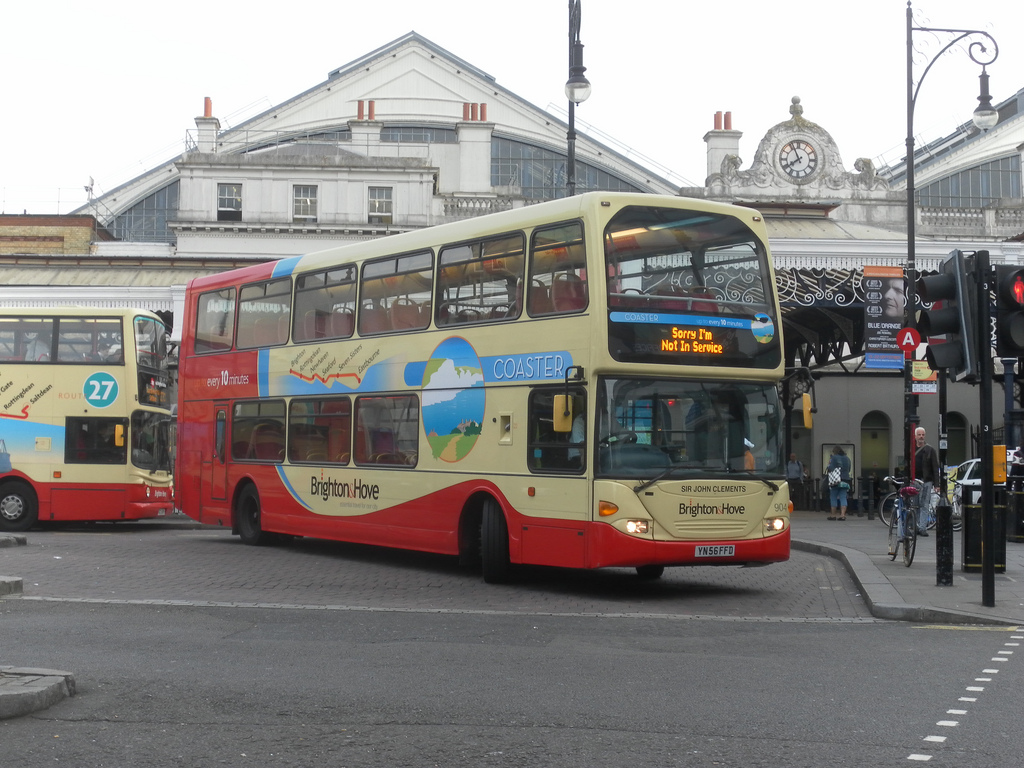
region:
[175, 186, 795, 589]
A red and beige double deck bus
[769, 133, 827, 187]
roman numeral clock on top of a building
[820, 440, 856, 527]
a woman wearing blue and carrying a white hand bag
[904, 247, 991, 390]
a three color traffic light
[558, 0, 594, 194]
street light with a hanging glass globe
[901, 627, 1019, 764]
white crosswalk lines painted on the street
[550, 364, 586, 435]
side view mirror of a double deck bus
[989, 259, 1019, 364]
a two color traffic light with the red light on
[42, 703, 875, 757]
long crack in the middle of the street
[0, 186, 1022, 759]
Two double decker buses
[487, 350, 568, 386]
Word coaster on the side of the bus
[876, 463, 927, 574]
bicycle on the sidewalk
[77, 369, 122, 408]
Number 27 on the bus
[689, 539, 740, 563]
White and black rectangular licence plate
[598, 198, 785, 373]
Windshield on the upper deck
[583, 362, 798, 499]
Windshield has two wipers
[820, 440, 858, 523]
Woman is standing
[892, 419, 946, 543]
Guy wearing jeans standing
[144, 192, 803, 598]
double deck bus on road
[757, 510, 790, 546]
left headlight on bus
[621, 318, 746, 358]
display module on bus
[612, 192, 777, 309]
top deck windshield on bus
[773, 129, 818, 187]
clock on building behind bus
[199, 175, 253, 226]
window on the building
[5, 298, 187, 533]
Yellow and red bus is double decker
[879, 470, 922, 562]
Bike chained to a pole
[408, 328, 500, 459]
advertisement on the bus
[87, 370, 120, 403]
number 27 on the bus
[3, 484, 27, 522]
silver rim on the bus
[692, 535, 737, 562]
license plate on the bus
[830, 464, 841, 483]
woman holding a black and white purse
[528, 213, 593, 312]
glass window on the yellow bus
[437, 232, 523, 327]
glass window on the yellow bus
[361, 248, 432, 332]
glass window on the yellow bus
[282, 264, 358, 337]
glass window on the yellow bus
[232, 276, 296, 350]
glass window on the yellow bus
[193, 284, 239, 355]
glass window on the yellow bus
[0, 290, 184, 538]
a bus with the number 27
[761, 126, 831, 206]
a clock on the building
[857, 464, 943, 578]
a bicycle by the post on the right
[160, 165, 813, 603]
a red tan and blue bus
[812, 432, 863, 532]
a woman carrying a white bag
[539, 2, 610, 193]
a light hanging over the bus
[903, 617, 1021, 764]
white dotted line on the street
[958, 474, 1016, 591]
a black trash can on the sidewalk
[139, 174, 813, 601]
double deck bus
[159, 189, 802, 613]
yellow and red double deck bus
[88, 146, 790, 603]
bus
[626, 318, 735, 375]
orange sign on bus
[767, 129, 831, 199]
black and white clock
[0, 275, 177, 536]
double deck bus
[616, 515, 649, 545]
white head light of bus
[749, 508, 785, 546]
white head light of bus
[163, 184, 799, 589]
red and cream bus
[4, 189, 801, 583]
two buses on a city street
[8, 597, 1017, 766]
a gray paved roadway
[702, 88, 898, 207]
clock in a decorative tower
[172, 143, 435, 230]
white building with three windows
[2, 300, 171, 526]
bus with the number 27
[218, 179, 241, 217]
A window on a building.